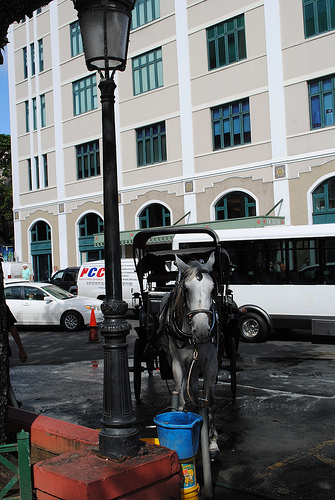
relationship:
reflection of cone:
[89, 344, 100, 371] [89, 308, 98, 329]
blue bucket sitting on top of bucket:
[157, 409, 201, 447] [180, 459, 200, 495]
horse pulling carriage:
[157, 248, 231, 452] [124, 219, 248, 475]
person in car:
[23, 288, 36, 300] [0, 278, 105, 331]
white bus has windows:
[236, 227, 309, 313] [179, 236, 331, 287]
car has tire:
[0, 252, 101, 330] [64, 309, 85, 322]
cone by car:
[79, 295, 117, 345] [3, 257, 115, 343]